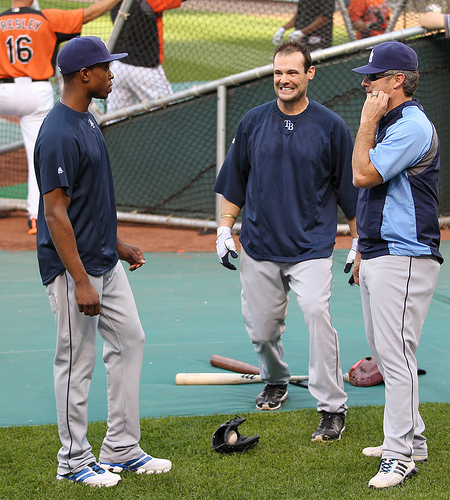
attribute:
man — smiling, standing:
[188, 23, 351, 424]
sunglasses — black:
[356, 68, 393, 91]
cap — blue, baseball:
[363, 32, 425, 76]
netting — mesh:
[169, 21, 234, 72]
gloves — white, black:
[202, 202, 252, 271]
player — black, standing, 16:
[27, 39, 156, 441]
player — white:
[174, 42, 371, 286]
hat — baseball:
[60, 24, 133, 75]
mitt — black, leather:
[211, 403, 272, 465]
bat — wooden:
[170, 360, 239, 403]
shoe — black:
[247, 370, 368, 451]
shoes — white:
[337, 420, 436, 487]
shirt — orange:
[0, 5, 98, 86]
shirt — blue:
[207, 105, 364, 270]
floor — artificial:
[155, 348, 260, 396]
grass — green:
[253, 429, 347, 455]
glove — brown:
[340, 348, 394, 387]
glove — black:
[217, 396, 269, 448]